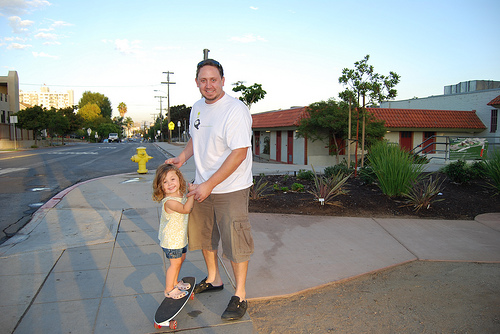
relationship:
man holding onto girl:
[161, 57, 257, 321] [153, 167, 203, 298]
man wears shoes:
[161, 57, 257, 321] [188, 276, 248, 326]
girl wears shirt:
[151, 163, 188, 301] [153, 192, 193, 247]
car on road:
[108, 133, 120, 143] [0, 143, 181, 244]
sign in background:
[160, 116, 180, 134] [4, 72, 496, 158]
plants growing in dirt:
[358, 135, 436, 211] [254, 175, 496, 218]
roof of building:
[350, 105, 493, 133] [247, 106, 490, 176]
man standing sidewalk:
[161, 57, 257, 321] [0, 167, 498, 330]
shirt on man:
[187, 93, 254, 194] [167, 56, 257, 331]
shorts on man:
[188, 181, 252, 271] [161, 57, 257, 321]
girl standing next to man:
[149, 160, 206, 306] [161, 57, 257, 321]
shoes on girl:
[163, 277, 199, 301] [151, 163, 188, 301]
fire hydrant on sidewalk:
[130, 147, 154, 175] [0, 167, 498, 330]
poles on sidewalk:
[146, 67, 177, 142] [150, 130, 305, 184]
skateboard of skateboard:
[151, 274, 199, 332] [145, 268, 200, 331]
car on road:
[99, 133, 122, 145] [2, 132, 174, 249]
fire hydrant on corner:
[130, 147, 154, 175] [82, 159, 193, 208]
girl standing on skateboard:
[149, 160, 206, 306] [145, 267, 208, 327]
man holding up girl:
[168, 57, 281, 327] [151, 163, 188, 301]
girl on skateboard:
[151, 163, 188, 301] [155, 273, 200, 332]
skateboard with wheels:
[146, 274, 206, 332] [148, 291, 204, 331]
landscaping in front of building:
[256, 145, 498, 219] [245, 98, 495, 180]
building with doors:
[245, 98, 495, 180] [398, 129, 444, 158]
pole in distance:
[157, 65, 188, 148] [139, 61, 197, 149]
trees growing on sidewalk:
[20, 85, 131, 148] [3, 125, 78, 165]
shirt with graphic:
[187, 93, 252, 200] [184, 115, 210, 140]